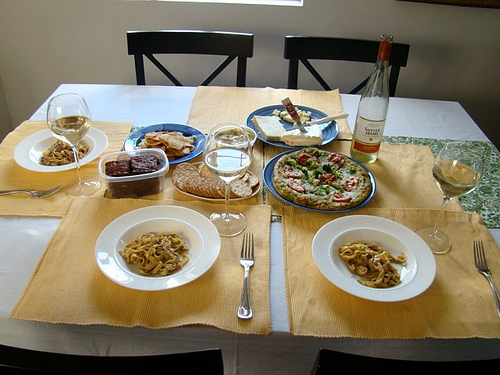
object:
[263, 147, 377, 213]
pizza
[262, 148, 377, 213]
blue plate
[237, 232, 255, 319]
fork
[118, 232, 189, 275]
food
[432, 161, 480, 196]
wine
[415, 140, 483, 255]
glass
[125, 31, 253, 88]
chair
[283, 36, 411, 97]
chair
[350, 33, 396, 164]
white wine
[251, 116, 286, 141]
bread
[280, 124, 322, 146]
butter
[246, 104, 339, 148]
plate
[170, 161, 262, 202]
crackers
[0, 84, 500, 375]
table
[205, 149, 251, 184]
wine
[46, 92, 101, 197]
glass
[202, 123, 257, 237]
glass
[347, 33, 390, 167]
bottle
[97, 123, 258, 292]
dishes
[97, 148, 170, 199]
brownies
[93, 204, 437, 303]
bowls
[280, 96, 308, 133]
handle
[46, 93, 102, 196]
wine glass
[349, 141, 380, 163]
wine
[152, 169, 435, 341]
everyone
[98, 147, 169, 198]
rectangular